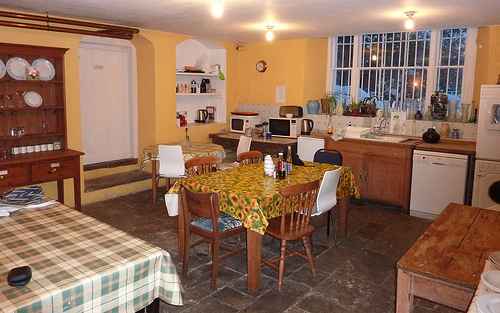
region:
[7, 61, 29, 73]
WHITE PLATES ON TOP SHELF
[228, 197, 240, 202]
YELLOW FLOWERS ON THE TABLE CLOTH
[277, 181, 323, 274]
CHAIR IS MADE OUT OF WOOD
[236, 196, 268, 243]
TABLE CLOTH ON THE TABLE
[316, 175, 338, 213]
BACK OF CHAIR IS WHITE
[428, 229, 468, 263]
TABLE IS MADE OUT OF WOOD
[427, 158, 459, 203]
DISHWASHER IS IN CORNER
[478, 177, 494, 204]
WASHER IS ON THE BOTTOM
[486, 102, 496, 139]
DRYER IS SITTING ON TOP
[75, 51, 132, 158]
DOORWAY IS ALL WHITE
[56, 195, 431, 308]
grey tile on the floor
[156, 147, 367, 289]
a wooden kitchen table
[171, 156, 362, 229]
a tablecloth with sunflowers on it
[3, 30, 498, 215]
walls painted yellow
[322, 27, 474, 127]
window above kitchen sink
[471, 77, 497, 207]
stacked washer and dryer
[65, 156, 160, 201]
steps leading up to a door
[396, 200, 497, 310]
wooden table on the right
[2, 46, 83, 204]
a hutch with china displayed on it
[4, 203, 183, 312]
a work table with a tablecloth on it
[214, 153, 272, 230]
the table clothe has flowers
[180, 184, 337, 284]
the chairs are made of wood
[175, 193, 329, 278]
the chairsa re brown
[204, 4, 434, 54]
lights are on the ceiling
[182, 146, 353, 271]
five chairs are around the table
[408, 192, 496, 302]
the table is wooden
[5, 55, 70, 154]
utensils are on the cabinet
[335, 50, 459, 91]
trees are on the outside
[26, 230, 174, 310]
table clothe is white and grey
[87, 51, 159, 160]
the door is white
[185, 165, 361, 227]
The sunflower table cloth.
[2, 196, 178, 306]
The plaid table cloth.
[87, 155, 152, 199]
The steps in front of the door.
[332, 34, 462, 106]
The window above the sink.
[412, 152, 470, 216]
The dishwasher near the sink.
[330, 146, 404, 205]
The cabinets below the sink.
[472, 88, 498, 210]
The compact washer and dryer on the right.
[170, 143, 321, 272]
The wooden chairs around the table.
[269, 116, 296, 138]
The microwave on the table.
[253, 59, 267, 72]
The clock hanging on the wall.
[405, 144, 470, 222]
White dishwasher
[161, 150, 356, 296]
Kitchen table with floral tablecloth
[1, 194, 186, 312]
Table with green and white checkered tablecloth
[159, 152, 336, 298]
Four wood chairs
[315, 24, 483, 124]
A white-trimmed window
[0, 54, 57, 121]
Plates in a wood hutch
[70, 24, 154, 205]
White door with a step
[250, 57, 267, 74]
A clock on the far wall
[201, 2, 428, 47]
Three lights on the ceiling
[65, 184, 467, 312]
Dark gray slate floor